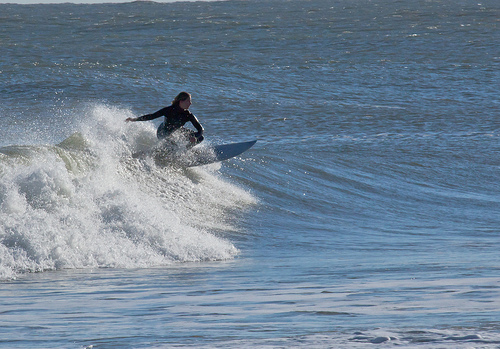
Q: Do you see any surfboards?
A: Yes, there is a surfboard.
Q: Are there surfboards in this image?
A: Yes, there is a surfboard.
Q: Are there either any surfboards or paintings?
A: Yes, there is a surfboard.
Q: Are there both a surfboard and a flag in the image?
A: No, there is a surfboard but no flags.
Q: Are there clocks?
A: No, there are no clocks.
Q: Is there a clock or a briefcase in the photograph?
A: No, there are no clocks or briefcases.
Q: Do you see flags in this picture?
A: No, there are no flags.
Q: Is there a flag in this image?
A: No, there are no flags.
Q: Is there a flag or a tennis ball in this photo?
A: No, there are no flags or tennis balls.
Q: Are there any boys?
A: No, there are no boys.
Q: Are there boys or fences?
A: No, there are no boys or fences.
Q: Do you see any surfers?
A: Yes, there is a surfer.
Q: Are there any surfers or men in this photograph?
A: Yes, there is a surfer.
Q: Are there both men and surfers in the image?
A: No, there is a surfer but no men.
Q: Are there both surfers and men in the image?
A: No, there is a surfer but no men.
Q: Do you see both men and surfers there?
A: No, there is a surfer but no men.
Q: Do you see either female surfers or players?
A: Yes, there is a female surfer.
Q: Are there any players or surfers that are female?
A: Yes, the surfer is female.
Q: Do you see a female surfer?
A: Yes, there is a female surfer.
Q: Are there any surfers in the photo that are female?
A: Yes, there is a surfer that is female.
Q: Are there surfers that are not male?
A: Yes, there is a female surfer.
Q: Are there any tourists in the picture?
A: No, there are no tourists.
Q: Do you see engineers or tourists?
A: No, there are no tourists or engineers.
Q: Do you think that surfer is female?
A: Yes, the surfer is female.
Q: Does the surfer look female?
A: Yes, the surfer is female.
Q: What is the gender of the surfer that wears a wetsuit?
A: The surfer is female.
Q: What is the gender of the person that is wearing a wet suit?
A: The surfer is female.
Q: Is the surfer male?
A: No, the surfer is female.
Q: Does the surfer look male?
A: No, the surfer is female.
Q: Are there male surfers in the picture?
A: No, there is a surfer but she is female.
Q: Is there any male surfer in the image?
A: No, there is a surfer but she is female.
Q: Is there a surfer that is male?
A: No, there is a surfer but she is female.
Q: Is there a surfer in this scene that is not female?
A: No, there is a surfer but she is female.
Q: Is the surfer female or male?
A: The surfer is female.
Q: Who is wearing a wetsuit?
A: The surfer is wearing a wetsuit.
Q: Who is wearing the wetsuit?
A: The surfer is wearing a wetsuit.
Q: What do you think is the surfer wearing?
A: The surfer is wearing a wetsuit.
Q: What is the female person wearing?
A: The surfer is wearing a wetsuit.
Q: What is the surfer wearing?
A: The surfer is wearing a wetsuit.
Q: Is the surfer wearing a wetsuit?
A: Yes, the surfer is wearing a wetsuit.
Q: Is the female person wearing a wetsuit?
A: Yes, the surfer is wearing a wetsuit.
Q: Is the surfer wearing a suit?
A: No, the surfer is wearing a wetsuit.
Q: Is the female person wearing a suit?
A: No, the surfer is wearing a wetsuit.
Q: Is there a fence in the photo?
A: No, there are no fences.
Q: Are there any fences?
A: No, there are no fences.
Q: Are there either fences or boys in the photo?
A: No, there are no fences or boys.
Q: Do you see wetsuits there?
A: Yes, there is a wetsuit.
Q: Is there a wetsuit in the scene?
A: Yes, there is a wetsuit.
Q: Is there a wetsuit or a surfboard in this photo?
A: Yes, there is a wetsuit.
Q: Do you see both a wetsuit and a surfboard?
A: Yes, there are both a wetsuit and a surfboard.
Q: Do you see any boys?
A: No, there are no boys.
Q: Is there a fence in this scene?
A: No, there are no fences.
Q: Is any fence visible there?
A: No, there are no fences.